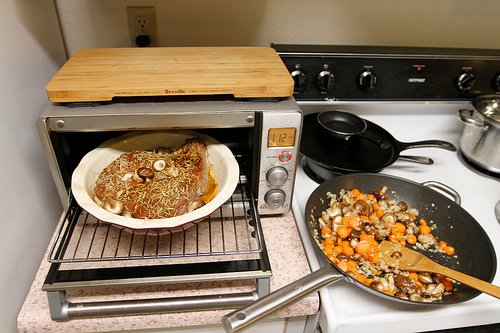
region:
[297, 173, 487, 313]
Food being cooked in a pan.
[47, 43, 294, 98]
A brown wooden cutting board.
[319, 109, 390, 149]
A very small frying pan.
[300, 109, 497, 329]
A white stovetop.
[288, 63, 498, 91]
Black knobs on a stove.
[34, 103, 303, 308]
A silver microwave oven.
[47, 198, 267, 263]
A silver rack to a microwave oven.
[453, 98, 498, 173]
A silver pot with a handle.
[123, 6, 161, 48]
A beige electrical outlet.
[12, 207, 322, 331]
A cream colored countertop.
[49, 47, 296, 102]
a thick wooden cutting board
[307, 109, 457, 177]
a black cast iron pan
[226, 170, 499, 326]
a silver and dark color wok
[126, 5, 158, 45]
an off-white electrical socket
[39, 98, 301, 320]
a stainless steel toaster oven with digital display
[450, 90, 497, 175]
a large stainless steel pot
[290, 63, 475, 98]
black knobs with white writing on stove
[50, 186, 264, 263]
metal rack of toaster oven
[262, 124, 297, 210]
user interface of toaster oven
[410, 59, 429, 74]
hot caution light on range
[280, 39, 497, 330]
a white and black stove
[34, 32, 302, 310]
a counter oven next a stove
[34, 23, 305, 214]
a board on top an oven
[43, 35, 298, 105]
a wood board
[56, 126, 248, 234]
a bowl of food in an oven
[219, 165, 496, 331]
a pan on a stove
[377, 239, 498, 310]
a brown wood spoon on a pan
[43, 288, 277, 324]
handle of oven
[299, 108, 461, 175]
black pan over a stove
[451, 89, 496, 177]
a pot with lid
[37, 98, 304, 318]
a metal toaster oven with digital display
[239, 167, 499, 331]
a large deep bottom skillet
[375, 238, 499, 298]
a wooden spatula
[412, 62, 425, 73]
a red caution light on stove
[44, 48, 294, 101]
a wooden cutting board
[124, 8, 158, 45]
an electrical socket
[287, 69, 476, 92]
black knobs on a stove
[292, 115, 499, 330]
a white top stove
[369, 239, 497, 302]
A wooden cooking spoon.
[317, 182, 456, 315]
Carrots cut up.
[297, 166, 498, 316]
Food cooking in a frying pan.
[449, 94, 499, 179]
A metal pot.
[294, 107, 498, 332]
The white top of a stove.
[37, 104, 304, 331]
A silver toaster oven.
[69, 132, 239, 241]
A round bowl.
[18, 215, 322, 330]
Beige colored countertops.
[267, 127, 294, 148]
A toaster oven clock.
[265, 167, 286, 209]
Toaster oven knobs.